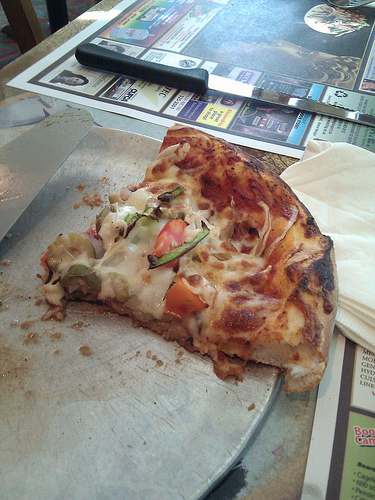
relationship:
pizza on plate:
[35, 124, 339, 395] [11, 135, 217, 484]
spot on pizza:
[292, 250, 335, 294] [72, 141, 318, 363]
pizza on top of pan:
[51, 113, 335, 378] [2, 118, 323, 498]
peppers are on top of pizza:
[116, 180, 210, 261] [64, 123, 342, 388]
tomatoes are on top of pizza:
[147, 206, 206, 323] [64, 123, 342, 388]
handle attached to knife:
[68, 31, 208, 87] [79, 35, 373, 132]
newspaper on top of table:
[26, 31, 373, 146] [6, 8, 373, 470]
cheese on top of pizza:
[68, 169, 253, 324] [35, 124, 339, 395]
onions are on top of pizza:
[57, 216, 126, 263] [35, 124, 339, 395]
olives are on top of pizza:
[49, 222, 109, 293] [35, 124, 339, 395]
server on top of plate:
[4, 96, 100, 280] [0, 124, 280, 500]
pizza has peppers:
[35, 124, 339, 395] [118, 184, 212, 265]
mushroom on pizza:
[63, 249, 102, 304] [51, 113, 335, 378]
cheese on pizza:
[107, 245, 177, 325] [51, 113, 335, 378]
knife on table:
[74, 42, 375, 130] [43, 2, 373, 471]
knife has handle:
[74, 42, 375, 130] [66, 29, 209, 101]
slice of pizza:
[31, 116, 350, 416] [35, 124, 339, 395]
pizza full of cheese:
[35, 124, 339, 395] [55, 163, 279, 330]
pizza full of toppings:
[35, 124, 339, 395] [82, 188, 212, 320]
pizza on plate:
[35, 124, 339, 395] [0, 124, 280, 500]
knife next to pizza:
[74, 42, 375, 130] [35, 124, 339, 395]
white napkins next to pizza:
[267, 127, 373, 357] [64, 123, 342, 388]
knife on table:
[62, 33, 372, 138] [6, 8, 373, 470]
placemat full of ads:
[23, 0, 373, 168] [82, 6, 368, 149]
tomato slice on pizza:
[153, 280, 220, 320] [35, 124, 339, 395]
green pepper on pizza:
[149, 212, 215, 267] [35, 124, 339, 395]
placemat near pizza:
[284, 318, 373, 498] [35, 124, 339, 395]